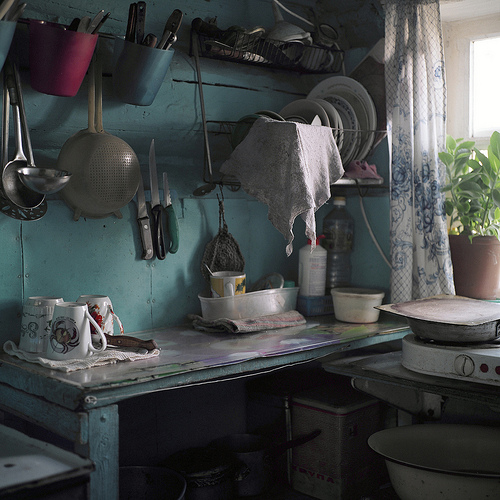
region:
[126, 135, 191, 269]
knives on the wall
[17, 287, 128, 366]
mugs on the wash rag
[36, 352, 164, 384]
a wash rag on the counter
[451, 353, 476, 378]
a knob for a hot palte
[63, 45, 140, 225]
a strainer on the wall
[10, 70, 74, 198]
A laddle on the wall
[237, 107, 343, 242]
a wash rag on the strainer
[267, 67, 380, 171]
dishes in the strainer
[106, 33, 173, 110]
A blue tub on the wall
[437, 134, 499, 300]
A potted plant in the window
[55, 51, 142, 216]
collander hanging from a hook on the wall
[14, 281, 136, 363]
three mugs sitting on the counter upside down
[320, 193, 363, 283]
large, clear plastic bottle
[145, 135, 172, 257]
long, sharp knife with a black hande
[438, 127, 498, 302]
green plant in a brown pot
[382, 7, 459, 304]
blue and white curtains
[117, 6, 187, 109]
blue bucket attached to the wall and holding various utenils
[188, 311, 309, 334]
discolored towel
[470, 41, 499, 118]
light streaming in the window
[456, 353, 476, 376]
white knob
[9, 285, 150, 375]
three white mugs that are upside down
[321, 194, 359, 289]
clear plastic bottle with a white cap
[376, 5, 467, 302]
blue and white curtain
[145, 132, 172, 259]
long knife with a black handle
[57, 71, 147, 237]
collander hanging on the wall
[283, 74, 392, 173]
plates in a rack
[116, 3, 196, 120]
blue container holding various utensils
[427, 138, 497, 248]
Pot is in the window sill.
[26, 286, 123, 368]
Coffee mugs are in the kitchen counter.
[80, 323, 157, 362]
Knife with wooden handle is between the mug.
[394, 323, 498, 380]
Stove is white color.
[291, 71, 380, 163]
Plates are arranged in rack.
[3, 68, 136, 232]
Vessels are hanging in the wall.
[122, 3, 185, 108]
Spoons are kept in the cup.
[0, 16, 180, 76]
Three cups are hanging in the wall.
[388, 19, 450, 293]
Curtain is blue and white color.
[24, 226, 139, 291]
Wall is green color.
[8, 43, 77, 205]
one pretty big ladle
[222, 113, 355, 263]
one drip-dried dishrag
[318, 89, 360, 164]
a blue-patterned rimmed plate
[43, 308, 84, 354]
a crab on a cup, upside down when right side up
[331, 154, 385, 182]
a pink thing, maybe an inside out dish glove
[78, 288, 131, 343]
a cup w/ a red spotted handle, looks - ah - slightly, ah - untoward, say - although it's probably just floral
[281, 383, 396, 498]
lidded basket, probably waste-, beneath counter, that has letters on it, maybe 'a v n a' [?]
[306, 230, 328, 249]
red cap-spout on white bottle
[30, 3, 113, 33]
mostly handles of mostly flatware in plastic red hanging thing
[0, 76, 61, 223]
spaghetti scooper, looks sorta kinda like the sugar silver strainer for drinking absinthe